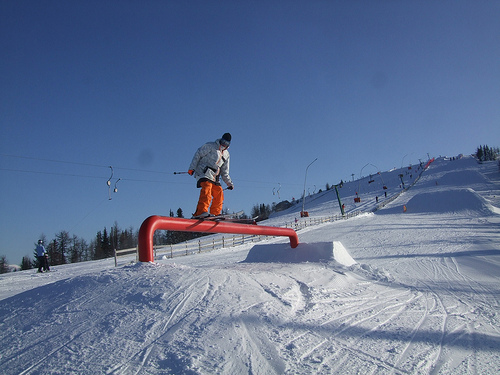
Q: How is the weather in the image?
A: It is cloudless.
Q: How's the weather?
A: It is cloudless.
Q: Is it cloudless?
A: Yes, it is cloudless.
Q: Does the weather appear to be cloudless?
A: Yes, it is cloudless.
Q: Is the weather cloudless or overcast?
A: It is cloudless.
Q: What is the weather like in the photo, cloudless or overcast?
A: It is cloudless.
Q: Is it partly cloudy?
A: No, it is cloudless.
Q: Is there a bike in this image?
A: No, there are no bikes.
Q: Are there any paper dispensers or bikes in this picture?
A: No, there are no bikes or paper dispensers.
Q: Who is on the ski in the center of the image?
A: The man is on the ski.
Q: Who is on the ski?
A: The man is on the ski.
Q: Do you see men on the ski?
A: Yes, there is a man on the ski.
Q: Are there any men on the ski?
A: Yes, there is a man on the ski.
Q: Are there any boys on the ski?
A: No, there is a man on the ski.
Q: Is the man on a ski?
A: Yes, the man is on a ski.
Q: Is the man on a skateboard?
A: No, the man is on a ski.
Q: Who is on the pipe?
A: The man is on the pipe.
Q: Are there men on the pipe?
A: Yes, there is a man on the pipe.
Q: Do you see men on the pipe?
A: Yes, there is a man on the pipe.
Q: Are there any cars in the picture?
A: No, there are no cars.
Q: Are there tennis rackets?
A: No, there are no tennis rackets.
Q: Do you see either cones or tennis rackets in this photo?
A: No, there are no tennis rackets or cones.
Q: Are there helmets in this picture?
A: No, there are no helmets.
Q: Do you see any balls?
A: No, there are no balls.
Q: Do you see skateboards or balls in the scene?
A: No, there are no balls or skateboards.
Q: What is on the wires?
A: The ski lift is on the wires.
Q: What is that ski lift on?
A: The ski lift is on the wires.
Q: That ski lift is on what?
A: The ski lift is on the wires.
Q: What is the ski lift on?
A: The ski lift is on the wires.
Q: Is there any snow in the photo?
A: Yes, there is snow.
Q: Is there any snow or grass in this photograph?
A: Yes, there is snow.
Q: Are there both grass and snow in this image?
A: No, there is snow but no grass.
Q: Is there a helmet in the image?
A: No, there are no helmets.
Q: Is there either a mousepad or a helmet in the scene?
A: No, there are no helmets or mouse pads.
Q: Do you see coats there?
A: Yes, there is a coat.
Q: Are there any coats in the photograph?
A: Yes, there is a coat.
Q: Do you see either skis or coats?
A: Yes, there is a coat.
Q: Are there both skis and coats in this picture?
A: Yes, there are both a coat and skis.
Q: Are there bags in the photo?
A: No, there are no bags.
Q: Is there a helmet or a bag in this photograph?
A: No, there are no bags or helmets.